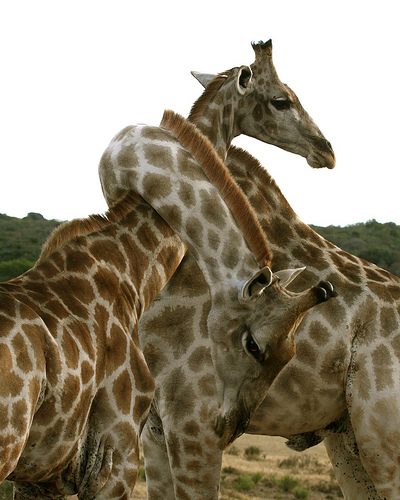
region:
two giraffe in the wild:
[4, 15, 396, 496]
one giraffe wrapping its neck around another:
[10, 28, 394, 496]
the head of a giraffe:
[230, 27, 348, 174]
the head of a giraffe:
[202, 257, 350, 450]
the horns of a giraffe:
[249, 35, 283, 60]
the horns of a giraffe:
[299, 277, 336, 317]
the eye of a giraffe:
[271, 92, 289, 114]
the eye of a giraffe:
[239, 327, 263, 360]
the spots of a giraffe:
[4, 283, 125, 443]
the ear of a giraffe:
[232, 266, 277, 305]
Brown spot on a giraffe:
[45, 329, 79, 371]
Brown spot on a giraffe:
[77, 355, 97, 397]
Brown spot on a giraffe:
[104, 367, 143, 415]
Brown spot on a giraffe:
[60, 244, 91, 277]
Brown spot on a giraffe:
[88, 236, 140, 278]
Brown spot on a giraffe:
[122, 229, 160, 294]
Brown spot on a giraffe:
[132, 218, 161, 252]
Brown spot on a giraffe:
[153, 241, 181, 281]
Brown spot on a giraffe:
[8, 332, 36, 383]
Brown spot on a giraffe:
[53, 369, 83, 414]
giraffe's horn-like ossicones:
[248, 37, 272, 71]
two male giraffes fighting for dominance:
[0, 39, 396, 498]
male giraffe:
[98, 108, 398, 496]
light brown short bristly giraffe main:
[161, 110, 269, 266]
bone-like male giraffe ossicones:
[292, 280, 333, 304]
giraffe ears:
[241, 264, 303, 301]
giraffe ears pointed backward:
[190, 36, 335, 169]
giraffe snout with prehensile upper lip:
[212, 408, 248, 448]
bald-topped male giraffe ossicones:
[300, 277, 333, 309]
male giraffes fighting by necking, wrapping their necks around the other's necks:
[3, 39, 396, 497]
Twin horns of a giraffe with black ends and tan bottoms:
[293, 278, 337, 312]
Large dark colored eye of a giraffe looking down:
[228, 326, 268, 373]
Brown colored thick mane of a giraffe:
[192, 127, 244, 208]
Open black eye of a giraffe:
[260, 85, 293, 119]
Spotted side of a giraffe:
[54, 279, 131, 381]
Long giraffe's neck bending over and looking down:
[166, 154, 227, 245]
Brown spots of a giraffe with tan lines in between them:
[280, 224, 361, 287]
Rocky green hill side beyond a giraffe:
[0, 206, 45, 264]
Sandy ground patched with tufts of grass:
[232, 431, 323, 498]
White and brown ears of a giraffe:
[192, 67, 248, 96]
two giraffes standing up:
[2, 36, 398, 498]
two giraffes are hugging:
[0, 41, 396, 498]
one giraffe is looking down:
[204, 260, 338, 450]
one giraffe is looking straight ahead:
[187, 36, 337, 173]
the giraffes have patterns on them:
[2, 39, 392, 497]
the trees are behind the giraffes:
[0, 209, 58, 249]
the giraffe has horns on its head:
[187, 35, 336, 171]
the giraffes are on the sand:
[2, 37, 393, 498]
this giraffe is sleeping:
[201, 264, 334, 449]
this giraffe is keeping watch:
[188, 36, 337, 176]